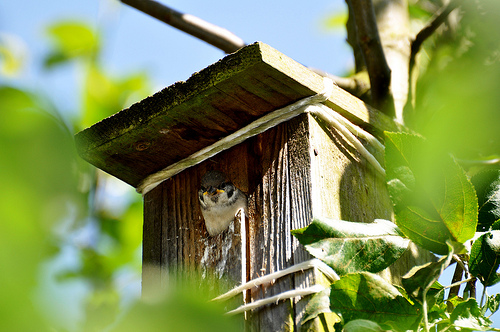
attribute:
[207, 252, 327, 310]
rope — white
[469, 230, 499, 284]
leaf — green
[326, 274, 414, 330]
leaf — green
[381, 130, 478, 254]
leaf — green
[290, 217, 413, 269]
leaf — green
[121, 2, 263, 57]
branch — thin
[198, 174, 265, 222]
feathers — white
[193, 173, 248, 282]
bird — yellow and dark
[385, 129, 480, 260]
leaf — green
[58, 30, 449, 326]
birdhouse — thick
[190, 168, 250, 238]
bird — white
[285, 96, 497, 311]
leaves — blurry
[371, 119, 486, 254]
leaf — green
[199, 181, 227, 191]
eyes — small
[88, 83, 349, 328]
birdhouse — wood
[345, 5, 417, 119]
tree trunk — thick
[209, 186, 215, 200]
beak — dark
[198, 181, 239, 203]
markings — orange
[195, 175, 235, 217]
head — dark